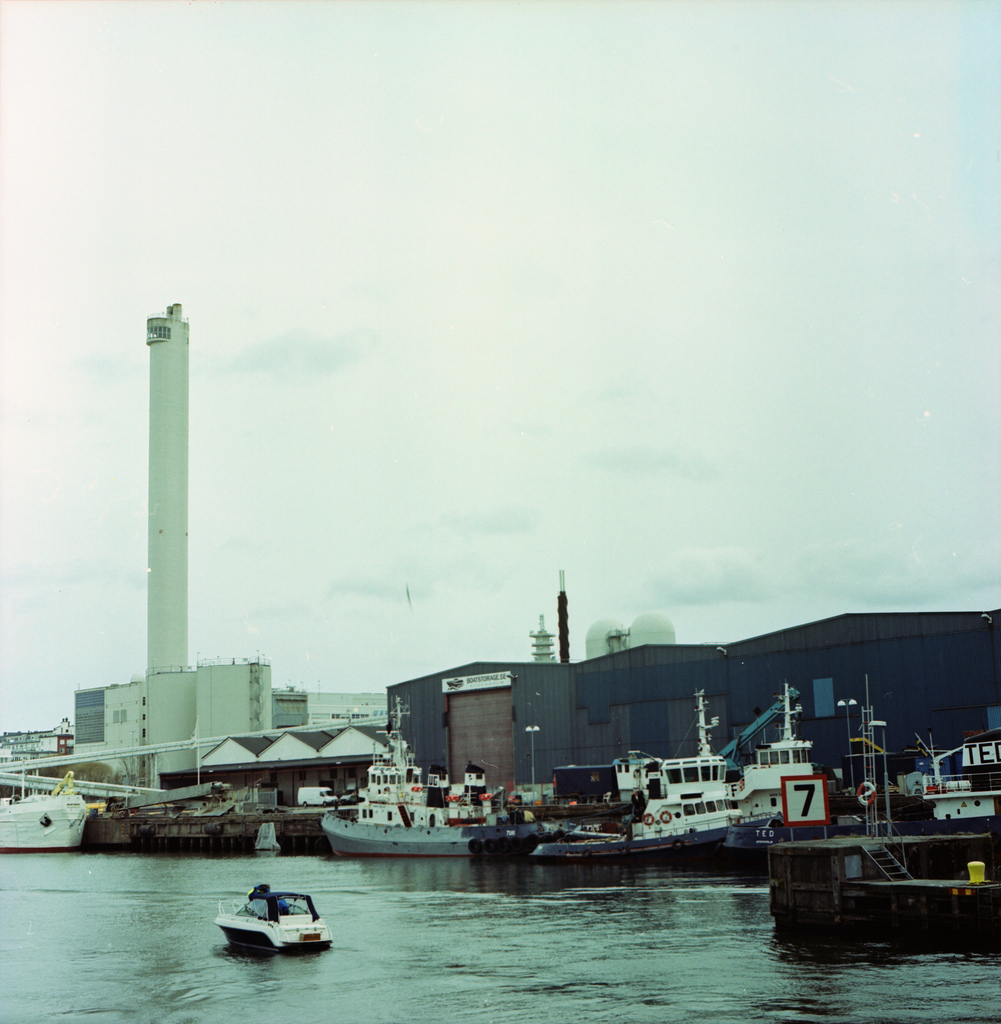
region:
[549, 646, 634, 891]
A person eating a orange.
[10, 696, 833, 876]
a group of boats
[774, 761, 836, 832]
a white and red sign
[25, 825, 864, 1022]
a body of water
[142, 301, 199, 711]
a large white tower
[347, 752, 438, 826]
white top of boat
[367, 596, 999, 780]
building on the side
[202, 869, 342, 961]
a small white and black boat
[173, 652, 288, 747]
a large white cylinder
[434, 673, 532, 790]
door on the building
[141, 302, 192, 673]
the tall white tower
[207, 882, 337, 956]
the white boat floating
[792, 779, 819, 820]
the black number 7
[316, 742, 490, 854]
the white tugboat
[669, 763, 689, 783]
the window of the tugboat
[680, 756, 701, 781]
the window of the tugboat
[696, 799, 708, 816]
the window of the tugboat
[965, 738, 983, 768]
the black letter t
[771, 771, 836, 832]
Square sign attached to poles.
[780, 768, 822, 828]
Black number 7 on sign.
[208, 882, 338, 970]
Blue and white boat in water.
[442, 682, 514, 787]
Large door on building.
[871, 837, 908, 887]
Stairs leading up to next level.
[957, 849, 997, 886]
Yellow can sitting on edge.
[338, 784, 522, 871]
Large boat in water.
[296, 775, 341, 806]
White van parked near building.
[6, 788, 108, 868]
Large white ship docked close to building.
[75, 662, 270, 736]
A building in a city.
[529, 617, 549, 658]
A building in a city.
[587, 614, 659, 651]
A building in a city.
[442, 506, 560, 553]
A cloud in the sky.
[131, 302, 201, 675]
tall tower on building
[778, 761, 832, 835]
sign on platform reads 7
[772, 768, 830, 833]
sign on top of platform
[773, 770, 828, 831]
sign on platform is red and white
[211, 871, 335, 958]
small boat in water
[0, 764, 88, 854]
docked boat is white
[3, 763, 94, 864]
white boat is docked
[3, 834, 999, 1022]
body of water is mostly calm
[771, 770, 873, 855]
black number on red and white sign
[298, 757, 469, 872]
white boat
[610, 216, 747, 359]
white clouds in blue sky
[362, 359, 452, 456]
white clouds in blue sky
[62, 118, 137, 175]
white clouds in blue sky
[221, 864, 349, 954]
white boat in water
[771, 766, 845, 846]
black white and red number sign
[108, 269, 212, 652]
white tower of building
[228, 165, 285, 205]
white clouds in blue sky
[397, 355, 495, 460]
white clouds in blue sky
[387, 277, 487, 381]
white clouds in blue sky